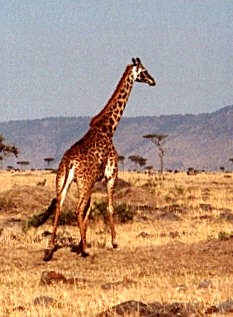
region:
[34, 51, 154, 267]
a giraffe in the wild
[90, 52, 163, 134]
giraffe facing the right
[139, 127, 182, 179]
a tree with tall leaves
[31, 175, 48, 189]
an animal in the distance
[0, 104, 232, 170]
hills rising in the background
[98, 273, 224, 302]
dried grass on the ground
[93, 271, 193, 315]
rocks on the terrain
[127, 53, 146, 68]
knobs on the giraffes head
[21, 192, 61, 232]
hair on the tail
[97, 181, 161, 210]
a mound of dirt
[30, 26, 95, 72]
The sky is blue.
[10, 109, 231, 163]
Mountain in the background.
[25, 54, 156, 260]
The giraffe is standing.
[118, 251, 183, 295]
The ground is brown.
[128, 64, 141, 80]
White on the neck.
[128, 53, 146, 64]
Horns on the head.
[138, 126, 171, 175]
Tree in the background.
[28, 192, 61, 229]
Hair on the end of the tail.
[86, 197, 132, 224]
Grass on the ground.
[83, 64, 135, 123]
Mane on the neck.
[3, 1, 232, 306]
the photo is blurry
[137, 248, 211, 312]
the grass is yellow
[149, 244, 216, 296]
the grass is dry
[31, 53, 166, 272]
the giraffe is tall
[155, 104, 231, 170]
the mountain is far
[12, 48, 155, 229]
the giraffe is spotted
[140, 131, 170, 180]
the tree with green leaves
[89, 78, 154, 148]
the neck of the giraffe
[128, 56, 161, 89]
the head of the giraffe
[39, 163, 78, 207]
the tail of the giraffe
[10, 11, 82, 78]
The sky is blue.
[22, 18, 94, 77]
The sky is clear.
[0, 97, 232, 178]
Mountains are in the background.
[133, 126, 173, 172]
The trees are tall.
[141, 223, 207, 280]
The grass is brown.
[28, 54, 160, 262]
The giraffe is tall.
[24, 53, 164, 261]
The giraffe is brown and white.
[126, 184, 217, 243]
The ground looks rough.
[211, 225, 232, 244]
A few green plants are on the ground.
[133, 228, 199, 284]
The grass is dry.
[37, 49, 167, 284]
giraffe walking away in field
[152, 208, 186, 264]
dry grass in field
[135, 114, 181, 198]
tall skinny trees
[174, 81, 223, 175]
mountains in the skyline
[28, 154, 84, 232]
giraffe wagging tail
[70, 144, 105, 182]
detailed pattern of giraffe fur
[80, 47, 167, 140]
stripe of hair down neck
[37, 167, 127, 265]
four very long legs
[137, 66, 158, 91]
darker fur around face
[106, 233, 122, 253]
darker fur near feet